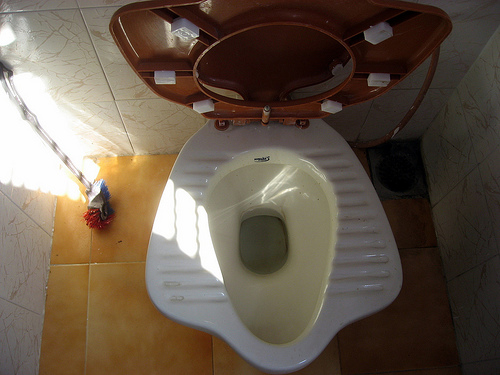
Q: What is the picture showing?
A: It is showing a bathroom.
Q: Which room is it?
A: It is a bathroom.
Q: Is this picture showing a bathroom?
A: Yes, it is showing a bathroom.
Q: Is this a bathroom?
A: Yes, it is a bathroom.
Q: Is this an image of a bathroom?
A: Yes, it is showing a bathroom.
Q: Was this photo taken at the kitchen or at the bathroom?
A: It was taken at the bathroom.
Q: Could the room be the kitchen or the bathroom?
A: It is the bathroom.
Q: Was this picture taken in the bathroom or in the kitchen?
A: It was taken at the bathroom.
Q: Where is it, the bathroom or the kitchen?
A: It is the bathroom.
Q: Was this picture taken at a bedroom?
A: No, the picture was taken in a bathroom.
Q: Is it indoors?
A: Yes, it is indoors.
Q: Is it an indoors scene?
A: Yes, it is indoors.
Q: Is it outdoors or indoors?
A: It is indoors.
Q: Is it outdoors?
A: No, it is indoors.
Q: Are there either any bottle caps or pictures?
A: No, there are no pictures or bottle caps.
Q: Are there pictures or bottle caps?
A: No, there are no pictures or bottle caps.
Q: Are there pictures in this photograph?
A: No, there are no pictures.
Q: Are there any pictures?
A: No, there are no pictures.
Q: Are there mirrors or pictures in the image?
A: No, there are no pictures or mirrors.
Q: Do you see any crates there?
A: No, there are no crates.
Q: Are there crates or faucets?
A: No, there are no crates or faucets.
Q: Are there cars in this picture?
A: No, there are no cars.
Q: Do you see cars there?
A: No, there are no cars.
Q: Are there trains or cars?
A: No, there are no cars or trains.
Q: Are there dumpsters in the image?
A: No, there are no dumpsters.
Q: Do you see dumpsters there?
A: No, there are no dumpsters.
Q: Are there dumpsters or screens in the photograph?
A: No, there are no dumpsters or screens.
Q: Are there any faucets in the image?
A: No, there are no faucets.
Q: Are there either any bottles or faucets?
A: No, there are no faucets or bottles.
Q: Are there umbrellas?
A: No, there are no umbrellas.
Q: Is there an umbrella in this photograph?
A: No, there are no umbrellas.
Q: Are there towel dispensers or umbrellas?
A: No, there are no umbrellas or towel dispensers.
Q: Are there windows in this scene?
A: Yes, there is a window.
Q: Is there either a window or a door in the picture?
A: Yes, there is a window.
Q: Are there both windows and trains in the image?
A: No, there is a window but no trains.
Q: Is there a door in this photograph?
A: No, there are no doors.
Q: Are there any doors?
A: No, there are no doors.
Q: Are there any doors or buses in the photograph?
A: No, there are no doors or buses.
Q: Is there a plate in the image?
A: Yes, there is a plate.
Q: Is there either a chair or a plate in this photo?
A: Yes, there is a plate.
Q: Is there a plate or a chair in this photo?
A: Yes, there is a plate.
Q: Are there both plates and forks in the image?
A: No, there is a plate but no forks.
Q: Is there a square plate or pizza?
A: Yes, there is a square plate.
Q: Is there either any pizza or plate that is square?
A: Yes, the plate is square.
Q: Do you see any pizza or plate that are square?
A: Yes, the plate is square.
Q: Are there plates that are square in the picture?
A: Yes, there is a square plate.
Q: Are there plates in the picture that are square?
A: Yes, there is a plate that is square.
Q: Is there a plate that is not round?
A: Yes, there is a square plate.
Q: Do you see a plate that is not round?
A: Yes, there is a square plate.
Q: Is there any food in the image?
A: No, there is no food.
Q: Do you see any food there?
A: No, there is no food.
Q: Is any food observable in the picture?
A: No, there is no food.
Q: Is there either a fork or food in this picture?
A: No, there are no food or forks.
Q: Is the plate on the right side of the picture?
A: Yes, the plate is on the right of the image.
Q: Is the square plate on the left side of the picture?
A: No, the plate is on the right of the image.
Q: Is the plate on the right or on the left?
A: The plate is on the right of the image.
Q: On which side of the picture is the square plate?
A: The plate is on the right of the image.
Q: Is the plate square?
A: Yes, the plate is square.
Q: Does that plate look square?
A: Yes, the plate is square.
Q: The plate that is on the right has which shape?
A: The plate is square.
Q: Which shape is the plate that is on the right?
A: The plate is square.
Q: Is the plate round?
A: No, the plate is square.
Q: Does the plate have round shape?
A: No, the plate is square.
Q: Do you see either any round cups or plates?
A: No, there is a plate but it is square.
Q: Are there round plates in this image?
A: No, there is a plate but it is square.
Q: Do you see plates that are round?
A: No, there is a plate but it is square.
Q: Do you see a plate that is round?
A: No, there is a plate but it is square.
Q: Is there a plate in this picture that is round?
A: No, there is a plate but it is square.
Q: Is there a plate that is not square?
A: No, there is a plate but it is square.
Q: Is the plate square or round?
A: The plate is square.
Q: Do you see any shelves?
A: No, there are no shelves.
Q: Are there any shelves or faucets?
A: No, there are no shelves or faucets.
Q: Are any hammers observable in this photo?
A: No, there are no hammers.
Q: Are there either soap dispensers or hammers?
A: No, there are no hammers or soap dispensers.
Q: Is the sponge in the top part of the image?
A: Yes, the sponge is in the top of the image.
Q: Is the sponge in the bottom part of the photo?
A: No, the sponge is in the top of the image.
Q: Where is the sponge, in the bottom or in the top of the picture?
A: The sponge is in the top of the image.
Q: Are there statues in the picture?
A: No, there are no statues.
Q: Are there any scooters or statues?
A: No, there are no statues or scooters.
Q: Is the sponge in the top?
A: Yes, the sponge is in the top of the image.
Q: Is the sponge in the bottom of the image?
A: No, the sponge is in the top of the image.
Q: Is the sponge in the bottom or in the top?
A: The sponge is in the top of the image.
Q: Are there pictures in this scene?
A: No, there are no pictures.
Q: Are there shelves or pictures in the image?
A: No, there are no pictures or shelves.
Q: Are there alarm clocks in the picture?
A: No, there are no alarm clocks.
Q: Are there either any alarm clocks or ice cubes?
A: No, there are no alarm clocks or ice cubes.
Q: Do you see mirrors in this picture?
A: No, there are no mirrors.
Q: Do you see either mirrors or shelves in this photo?
A: No, there are no mirrors or shelves.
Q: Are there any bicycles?
A: No, there are no bicycles.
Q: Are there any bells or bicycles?
A: No, there are no bicycles or bells.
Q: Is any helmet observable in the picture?
A: No, there are no helmets.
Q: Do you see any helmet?
A: No, there are no helmets.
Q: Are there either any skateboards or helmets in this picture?
A: No, there are no helmets or skateboards.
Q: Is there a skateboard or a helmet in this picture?
A: No, there are no helmets or skateboards.